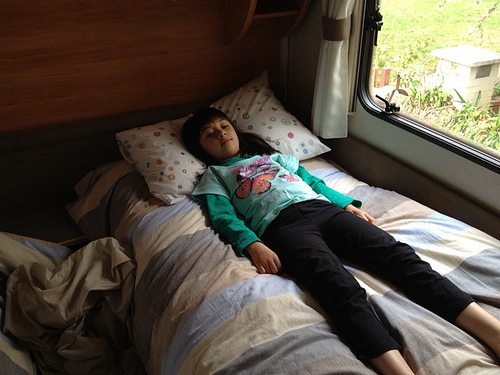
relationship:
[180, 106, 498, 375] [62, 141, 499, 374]
girl on bed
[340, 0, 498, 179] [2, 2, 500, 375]
window of trailer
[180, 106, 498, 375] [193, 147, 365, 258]
girl wearing shirts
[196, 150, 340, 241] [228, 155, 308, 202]
shirt has butterflies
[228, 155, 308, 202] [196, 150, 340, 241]
butterflies on shirt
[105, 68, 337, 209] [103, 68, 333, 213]
pillow has case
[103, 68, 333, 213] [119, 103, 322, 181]
case has spots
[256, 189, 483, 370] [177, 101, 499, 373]
pants on girl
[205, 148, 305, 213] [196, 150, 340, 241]
design on shirt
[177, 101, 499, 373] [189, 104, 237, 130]
girl has bangs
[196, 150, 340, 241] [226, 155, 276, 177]
shirt has writing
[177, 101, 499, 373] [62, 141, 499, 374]
girl on bed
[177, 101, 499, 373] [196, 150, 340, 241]
girl has shirt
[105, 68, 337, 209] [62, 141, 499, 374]
pillow on bed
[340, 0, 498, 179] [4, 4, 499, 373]
window on camper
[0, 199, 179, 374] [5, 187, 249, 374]
blankets on floor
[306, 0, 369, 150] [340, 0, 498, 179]
curtains on window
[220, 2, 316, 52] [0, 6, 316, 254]
shelf on wall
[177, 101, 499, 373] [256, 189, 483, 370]
girl wearing pants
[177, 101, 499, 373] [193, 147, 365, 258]
girl wearing top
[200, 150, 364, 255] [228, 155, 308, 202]
shirt has butterflies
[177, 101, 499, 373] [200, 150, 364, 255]
girl wearing shirt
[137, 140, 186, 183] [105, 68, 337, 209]
dots on pillow